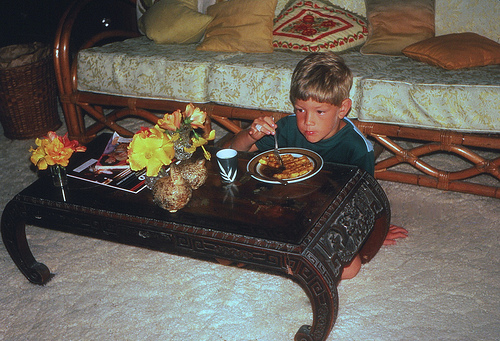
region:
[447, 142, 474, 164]
wooden bar on couch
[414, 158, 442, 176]
wooden bar on couch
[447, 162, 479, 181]
wooden bar on couch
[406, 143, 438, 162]
wooden bar on couch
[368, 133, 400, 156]
wooden bar on couch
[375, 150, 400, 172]
wooden bar on couch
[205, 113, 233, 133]
wooden bar on couch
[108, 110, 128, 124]
wooden bar on couch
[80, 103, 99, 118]
wooden bar on couch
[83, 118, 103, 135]
wooden bar on couch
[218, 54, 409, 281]
A little boy sitting on the floor eating breakfast.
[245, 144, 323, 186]
Waffles on a brown and white plate.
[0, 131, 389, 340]
Plate on top of a brown wooden coffee table.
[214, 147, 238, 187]
Cup with a leaf pattern next to the plate.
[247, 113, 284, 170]
A fork in the boy's hands.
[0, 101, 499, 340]
Plush white carpet on the floor.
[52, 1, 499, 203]
Brown bamboo framed sofa.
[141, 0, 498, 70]
Throw pillows on the sofa cushions.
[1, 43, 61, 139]
A wicker basket next to the sofa.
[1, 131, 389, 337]
a dark wooden coffee-table with legs that curve inward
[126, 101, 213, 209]
flower arrangement with a large prominent yellow flower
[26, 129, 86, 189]
small flower arrangement in a narrow container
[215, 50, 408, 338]
boy sitting on ground behind right half of coffee-table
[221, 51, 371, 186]
plate with food in front of boy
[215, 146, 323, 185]
small cup next to plate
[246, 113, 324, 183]
boy holding fork upright over plate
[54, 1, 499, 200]
lower section of a white and yellow couch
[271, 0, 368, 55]
red and green throw pillow with a floral design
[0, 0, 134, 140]
tall woven basket beside arm of couch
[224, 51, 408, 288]
A little boy sitting at a coffee table eating dinner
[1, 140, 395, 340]
A brown coffee table with curved legs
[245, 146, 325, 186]
Food on a blue and brown plate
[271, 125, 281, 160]
A silver spoon in a boys hand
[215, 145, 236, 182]
A black and white cup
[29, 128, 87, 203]
An orange flower in a black vase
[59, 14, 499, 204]
A sofa with a wooden base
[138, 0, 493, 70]
Brown and tan decorative pillows on a sofa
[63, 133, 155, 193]
A stack of magazines on a coffee table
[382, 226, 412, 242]
A boy's hand on white carpet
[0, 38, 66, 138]
a tall wicker basket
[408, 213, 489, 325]
a soft white carpet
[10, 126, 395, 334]
a decorative wood table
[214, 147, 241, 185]
a black and white cup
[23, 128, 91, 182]
a small flower arrangement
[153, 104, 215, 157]
flowers in a vase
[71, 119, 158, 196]
a pair of magazines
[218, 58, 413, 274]
a boy eating breakfast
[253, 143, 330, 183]
a plate of waffles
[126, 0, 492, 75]
a few throw pillows